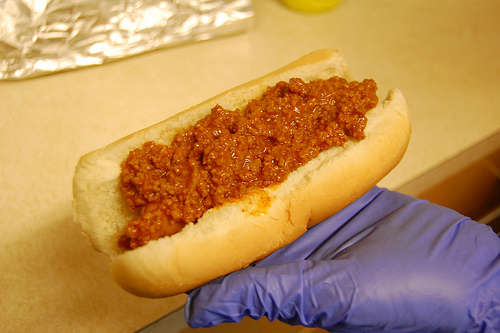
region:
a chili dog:
[48, 36, 422, 301]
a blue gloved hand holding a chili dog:
[71, 36, 496, 325]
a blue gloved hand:
[182, 170, 488, 325]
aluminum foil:
[6, 6, 256, 56]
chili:
[114, 69, 388, 231]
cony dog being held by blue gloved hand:
[76, 45, 429, 294]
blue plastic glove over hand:
[183, 175, 499, 330]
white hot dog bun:
[73, 44, 396, 292]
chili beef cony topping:
[123, 74, 391, 242]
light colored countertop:
[6, 5, 492, 320]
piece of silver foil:
[3, 5, 248, 82]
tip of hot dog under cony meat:
[118, 218, 163, 251]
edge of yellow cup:
[281, 0, 346, 12]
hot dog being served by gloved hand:
[63, 41, 495, 330]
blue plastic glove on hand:
[181, 183, 498, 329]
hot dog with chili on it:
[75, 49, 411, 296]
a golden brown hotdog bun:
[71, 47, 406, 298]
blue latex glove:
[186, 186, 498, 331]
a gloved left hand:
[186, 183, 499, 330]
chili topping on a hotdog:
[119, 72, 378, 249]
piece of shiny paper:
[0, 1, 258, 78]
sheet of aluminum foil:
[0, 0, 252, 80]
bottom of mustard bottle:
[277, 0, 341, 17]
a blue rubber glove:
[184, 187, 497, 332]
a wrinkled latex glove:
[185, 187, 497, 330]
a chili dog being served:
[75, 47, 412, 294]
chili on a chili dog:
[118, 76, 378, 241]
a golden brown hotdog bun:
[75, 44, 411, 298]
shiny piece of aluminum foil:
[0, 2, 257, 78]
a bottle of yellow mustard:
[274, 0, 340, 16]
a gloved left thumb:
[184, 259, 354, 329]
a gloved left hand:
[184, 187, 497, 332]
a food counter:
[0, 2, 498, 330]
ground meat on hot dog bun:
[69, 41, 419, 303]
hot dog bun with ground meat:
[62, 41, 426, 300]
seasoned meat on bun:
[57, 40, 424, 305]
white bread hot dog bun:
[60, 40, 417, 302]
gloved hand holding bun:
[179, 183, 496, 331]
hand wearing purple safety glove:
[166, 177, 498, 332]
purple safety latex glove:
[180, 183, 487, 330]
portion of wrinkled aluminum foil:
[5, 3, 261, 85]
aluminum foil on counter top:
[2, 2, 268, 84]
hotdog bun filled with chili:
[58, 57, 431, 287]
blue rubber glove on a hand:
[174, 187, 499, 331]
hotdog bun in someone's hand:
[48, 52, 406, 292]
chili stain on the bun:
[248, 188, 268, 216]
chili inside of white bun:
[70, 47, 412, 299]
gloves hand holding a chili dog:
[72, 45, 498, 331]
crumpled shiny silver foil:
[0, 0, 252, 85]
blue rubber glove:
[168, 189, 478, 321]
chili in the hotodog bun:
[109, 77, 379, 259]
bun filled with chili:
[59, 52, 409, 283]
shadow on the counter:
[10, 200, 151, 331]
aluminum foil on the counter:
[3, 1, 246, 83]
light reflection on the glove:
[360, 258, 471, 307]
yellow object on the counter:
[279, 0, 344, 20]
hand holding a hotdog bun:
[167, 186, 498, 332]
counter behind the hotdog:
[0, 2, 493, 330]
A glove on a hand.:
[192, 172, 492, 309]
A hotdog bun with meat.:
[64, 32, 416, 300]